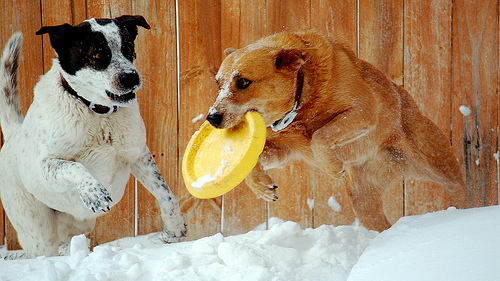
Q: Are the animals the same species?
A: Yes, all the animals are dogs.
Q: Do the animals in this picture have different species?
A: No, all the animals are dogs.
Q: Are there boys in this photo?
A: No, there are no boys.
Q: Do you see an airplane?
A: No, there are no airplanes.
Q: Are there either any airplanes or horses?
A: No, there are no airplanes or horses.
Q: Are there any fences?
A: Yes, there is a fence.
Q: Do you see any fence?
A: Yes, there is a fence.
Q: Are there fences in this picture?
A: Yes, there is a fence.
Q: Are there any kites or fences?
A: Yes, there is a fence.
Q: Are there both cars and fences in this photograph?
A: No, there is a fence but no cars.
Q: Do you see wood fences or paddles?
A: Yes, there is a wood fence.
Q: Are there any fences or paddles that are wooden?
A: Yes, the fence is wooden.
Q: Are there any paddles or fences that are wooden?
A: Yes, the fence is wooden.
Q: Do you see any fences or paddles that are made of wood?
A: Yes, the fence is made of wood.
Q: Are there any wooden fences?
A: Yes, there is a wood fence.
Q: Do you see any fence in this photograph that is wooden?
A: Yes, there is a fence that is wooden.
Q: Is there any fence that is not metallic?
A: Yes, there is a wooden fence.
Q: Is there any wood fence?
A: Yes, there is a fence that is made of wood.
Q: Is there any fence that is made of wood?
A: Yes, there is a fence that is made of wood.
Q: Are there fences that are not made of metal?
A: Yes, there is a fence that is made of wood.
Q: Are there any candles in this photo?
A: No, there are no candles.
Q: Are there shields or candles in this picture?
A: No, there are no candles or shields.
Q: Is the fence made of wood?
A: Yes, the fence is made of wood.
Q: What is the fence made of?
A: The fence is made of wood.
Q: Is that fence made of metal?
A: No, the fence is made of wood.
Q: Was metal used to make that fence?
A: No, the fence is made of wood.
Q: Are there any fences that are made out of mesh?
A: No, there is a fence but it is made of wood.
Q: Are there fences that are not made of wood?
A: No, there is a fence but it is made of wood.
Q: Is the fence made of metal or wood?
A: The fence is made of wood.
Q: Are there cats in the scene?
A: No, there are no cats.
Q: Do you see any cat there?
A: No, there are no cats.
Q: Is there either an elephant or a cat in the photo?
A: No, there are no cats or elephants.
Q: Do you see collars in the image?
A: Yes, there is a collar.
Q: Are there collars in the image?
A: Yes, there is a collar.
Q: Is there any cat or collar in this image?
A: Yes, there is a collar.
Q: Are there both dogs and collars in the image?
A: Yes, there are both a collar and a dog.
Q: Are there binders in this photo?
A: No, there are no binders.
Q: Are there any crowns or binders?
A: No, there are no binders or crowns.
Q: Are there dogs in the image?
A: Yes, there is a dog.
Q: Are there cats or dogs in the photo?
A: Yes, there is a dog.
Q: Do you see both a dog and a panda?
A: No, there is a dog but no pandas.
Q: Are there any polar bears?
A: No, there are no polar bears.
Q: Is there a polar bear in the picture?
A: No, there are no polar bears.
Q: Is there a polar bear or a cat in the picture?
A: No, there are no polar bears or cats.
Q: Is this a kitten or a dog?
A: This is a dog.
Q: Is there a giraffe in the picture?
A: No, there are no giraffes.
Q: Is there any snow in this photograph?
A: Yes, there is snow.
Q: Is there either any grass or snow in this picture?
A: Yes, there is snow.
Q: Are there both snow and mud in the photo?
A: No, there is snow but no mud.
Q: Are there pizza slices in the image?
A: No, there are no pizza slices.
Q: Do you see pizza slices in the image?
A: No, there are no pizza slices.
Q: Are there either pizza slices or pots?
A: No, there are no pizza slices or pots.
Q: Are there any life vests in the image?
A: No, there are no life vests.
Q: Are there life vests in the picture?
A: No, there are no life vests.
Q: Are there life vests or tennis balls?
A: No, there are no life vests or tennis balls.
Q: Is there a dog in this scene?
A: Yes, there is a dog.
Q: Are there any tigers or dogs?
A: Yes, there is a dog.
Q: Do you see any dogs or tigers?
A: Yes, there is a dog.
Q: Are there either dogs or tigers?
A: Yes, there is a dog.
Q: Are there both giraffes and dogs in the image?
A: No, there is a dog but no giraffes.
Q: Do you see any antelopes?
A: No, there are no antelopes.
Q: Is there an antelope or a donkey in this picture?
A: No, there are no antelopes or donkeys.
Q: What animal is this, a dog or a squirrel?
A: This is a dog.